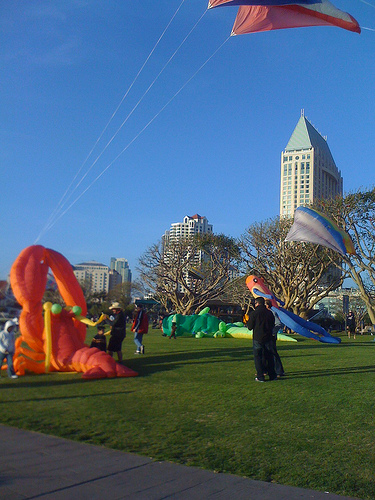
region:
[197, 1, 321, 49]
red kite in sky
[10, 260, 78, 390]
orange balloon on ground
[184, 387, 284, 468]
grass is dark green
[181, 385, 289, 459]
grass next to sidewalk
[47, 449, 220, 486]
sidewalk is dark grey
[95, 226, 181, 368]
people near large orange balloon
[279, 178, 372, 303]
grey balloon is flying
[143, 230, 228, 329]
bare tree behind balloons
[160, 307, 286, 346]
green balloon on ground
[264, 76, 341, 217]
tall blue and white building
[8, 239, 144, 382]
a large inflatable lobster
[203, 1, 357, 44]
a large red and white kite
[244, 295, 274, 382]
a man standing on field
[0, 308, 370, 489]
a patch of green grass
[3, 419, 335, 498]
a brick paved sidewalk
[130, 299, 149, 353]
a man walking on grass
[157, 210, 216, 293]
a tall white building in distance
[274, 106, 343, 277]
a tall building in distance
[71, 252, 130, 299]
a tall building in distance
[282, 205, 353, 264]
a colorful kite in air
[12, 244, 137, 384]
the big lobster air balloon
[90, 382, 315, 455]
the short lush green grass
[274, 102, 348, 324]
the tallest building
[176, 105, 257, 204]
the clear blue sky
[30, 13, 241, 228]
the three kite strings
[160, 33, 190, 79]
the kite string in the middle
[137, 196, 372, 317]
the trees lined up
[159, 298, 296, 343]
the large green air balloon on the ground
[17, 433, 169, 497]
the cement sidewalk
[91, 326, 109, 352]
the small child by the lobster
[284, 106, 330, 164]
green tower of a building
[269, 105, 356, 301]
green top towering building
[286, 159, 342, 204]
windows in the tower building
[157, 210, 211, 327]
round white building with red roofs on top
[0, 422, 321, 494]
grey sidewalk next to field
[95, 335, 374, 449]
green grassy field with people on it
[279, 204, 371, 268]
white and blue kite in tree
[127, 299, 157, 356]
person walking wearing a red coat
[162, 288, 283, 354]
huge green puppet on grass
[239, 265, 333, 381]
man holding an orange and blue kite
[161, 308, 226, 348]
the kite is bright green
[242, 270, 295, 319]
the kite is red orange and blue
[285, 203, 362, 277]
the kite is grey blue and yellow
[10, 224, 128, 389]
the kite is red green and yellow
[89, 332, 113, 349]
the shirt is black and orange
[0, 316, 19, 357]
the shirt is grey in color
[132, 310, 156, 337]
the coat is red black and grey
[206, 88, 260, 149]
the sky is blue and clear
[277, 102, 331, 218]
the building is teal and tan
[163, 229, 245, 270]
the tree has some green leaves on it